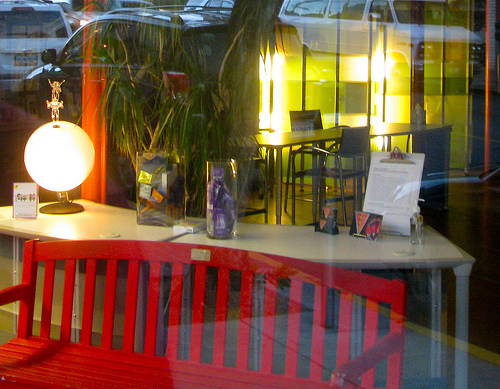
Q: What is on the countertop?
A: A lamp.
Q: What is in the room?
A: A red bench.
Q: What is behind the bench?
A: A table.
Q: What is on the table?
A: A round light.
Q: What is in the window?
A: A car reflection.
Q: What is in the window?
A: A red bench.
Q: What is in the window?
A: Reflection of a white van.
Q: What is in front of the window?
A: Red bench.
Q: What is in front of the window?
A: A red bench.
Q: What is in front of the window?
A: A red bench.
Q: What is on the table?
A: A yellow lamp.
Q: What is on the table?
A: A yellow lamp.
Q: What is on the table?
A: Jars.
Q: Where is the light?
A: In the table.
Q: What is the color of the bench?
A: Red.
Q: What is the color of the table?
A: White.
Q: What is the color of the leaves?
A: Green.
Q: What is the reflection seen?
A: Car.